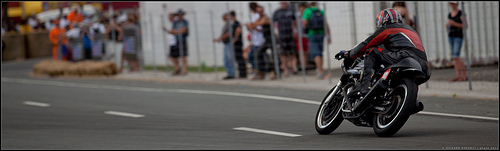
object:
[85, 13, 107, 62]
person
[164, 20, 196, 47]
clothing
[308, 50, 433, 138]
motorcycle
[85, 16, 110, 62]
woman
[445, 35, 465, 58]
jeans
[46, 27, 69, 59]
jumpsuits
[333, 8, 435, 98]
biker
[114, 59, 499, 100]
sidewalk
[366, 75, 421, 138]
tires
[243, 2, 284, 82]
person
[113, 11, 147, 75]
men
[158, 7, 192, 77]
people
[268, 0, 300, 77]
woman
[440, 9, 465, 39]
shirt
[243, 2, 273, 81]
person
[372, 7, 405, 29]
helmet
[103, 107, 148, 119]
lines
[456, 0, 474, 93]
pole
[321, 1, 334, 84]
pole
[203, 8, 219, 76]
pole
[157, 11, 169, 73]
pole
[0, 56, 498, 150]
ground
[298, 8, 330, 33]
backpack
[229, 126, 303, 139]
strip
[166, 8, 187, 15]
hat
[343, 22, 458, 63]
clothing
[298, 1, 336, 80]
man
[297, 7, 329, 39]
shirt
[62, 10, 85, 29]
orange suits